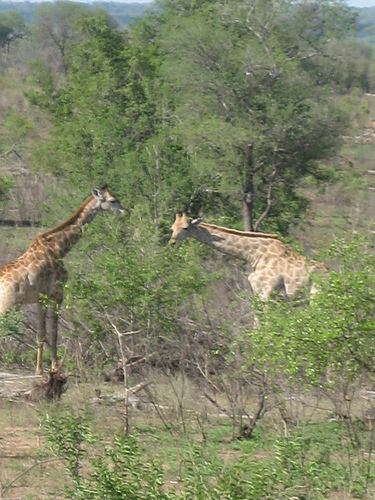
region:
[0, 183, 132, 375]
Adult giraffe on the left.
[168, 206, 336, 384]
Adult giraffe on the right.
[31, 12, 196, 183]
Tall leafy tree in the jungle.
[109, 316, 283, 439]
Dry leafless bush in the jungle.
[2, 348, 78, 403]
Dead fallen tree near giraffe.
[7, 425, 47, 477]
Dry ground with no grass.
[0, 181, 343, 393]
Two adult giraffes in the jungle.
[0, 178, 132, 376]
Giraffe with dark orange coloring.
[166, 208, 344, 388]
Giraffe with light orange coloring.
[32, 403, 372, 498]
Green leafy bush in the jungle.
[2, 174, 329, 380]
two giraffes among trees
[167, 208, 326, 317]
giraffe with neck bent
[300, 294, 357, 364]
green leaves on tree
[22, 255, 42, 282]
brown spots on giraffe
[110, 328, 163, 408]
branches with no leaves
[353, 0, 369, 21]
blue sky on the horizon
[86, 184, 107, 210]
ear on side of head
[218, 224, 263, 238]
mane on giraffe's neck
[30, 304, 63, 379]
two front legs on giraffe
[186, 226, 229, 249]
shadow on giraffe's neck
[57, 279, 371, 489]
these are shrubs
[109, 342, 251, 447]
these are dry shrubs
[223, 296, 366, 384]
these are green leafs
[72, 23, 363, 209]
these are trees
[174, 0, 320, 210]
these are branches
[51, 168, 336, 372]
these are giraffes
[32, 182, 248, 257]
the giraffes are grazing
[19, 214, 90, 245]
these are giraffes fur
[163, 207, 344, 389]
the giraffe are big in size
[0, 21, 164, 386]
the giraffe are standing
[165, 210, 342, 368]
light colored giraffe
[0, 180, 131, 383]
dark colored giraffe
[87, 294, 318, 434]
dead trees and bushes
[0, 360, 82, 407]
fallen down tree trunk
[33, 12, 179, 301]
healthy green tree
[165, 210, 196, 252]
giraffe facing towards camera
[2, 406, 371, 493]
arid grass and dirt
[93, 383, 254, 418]
dead branches and bush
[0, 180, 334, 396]
two giraffes in the plains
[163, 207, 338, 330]
giraffe eating brush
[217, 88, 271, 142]
branches of some trees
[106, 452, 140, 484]
leaves of some trees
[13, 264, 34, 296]
stomach of a giraffe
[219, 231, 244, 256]
neck of a giraffe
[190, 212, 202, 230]
ear of a giraffe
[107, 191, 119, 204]
eye of a giraffe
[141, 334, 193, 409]
part of some dry plants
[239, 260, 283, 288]
part of a front hip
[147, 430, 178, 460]
part part of the ground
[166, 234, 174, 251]
nose of a giraffe